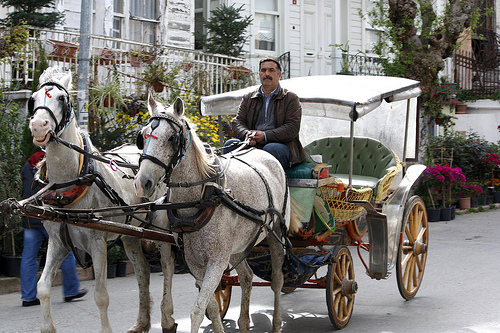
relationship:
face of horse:
[21, 79, 65, 150] [28, 77, 136, 262]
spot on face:
[44, 88, 54, 107] [21, 79, 65, 150]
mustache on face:
[261, 75, 274, 82] [257, 59, 280, 86]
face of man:
[257, 59, 280, 86] [215, 51, 338, 160]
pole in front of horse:
[64, 24, 108, 214] [28, 77, 136, 262]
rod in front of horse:
[82, 187, 180, 232] [28, 77, 136, 262]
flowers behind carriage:
[157, 86, 255, 154] [172, 39, 419, 255]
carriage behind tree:
[172, 39, 419, 255] [394, 14, 452, 134]